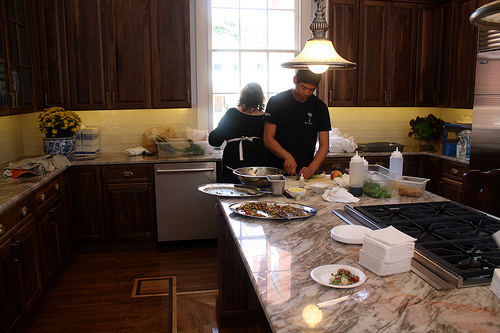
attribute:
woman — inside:
[208, 86, 279, 181]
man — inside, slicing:
[267, 69, 329, 174]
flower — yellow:
[36, 107, 88, 133]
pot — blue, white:
[41, 139, 75, 159]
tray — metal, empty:
[242, 199, 315, 225]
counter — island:
[220, 171, 444, 322]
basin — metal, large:
[231, 164, 284, 186]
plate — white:
[313, 258, 359, 292]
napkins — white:
[361, 212, 409, 281]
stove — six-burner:
[369, 199, 499, 282]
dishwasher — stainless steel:
[151, 162, 222, 240]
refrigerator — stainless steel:
[461, 10, 500, 186]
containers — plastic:
[152, 138, 213, 156]